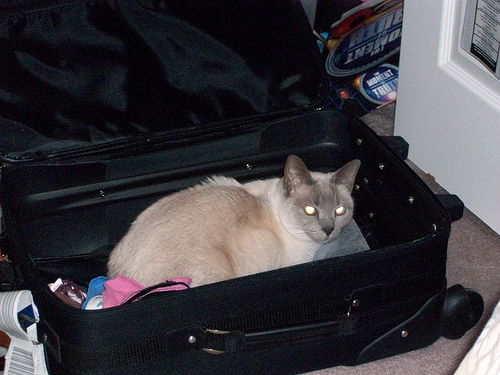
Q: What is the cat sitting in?
A: Suitcase.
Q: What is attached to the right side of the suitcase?
A: Wheels.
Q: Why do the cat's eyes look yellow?
A: Reflection.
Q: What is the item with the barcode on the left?
A: Luggage tag.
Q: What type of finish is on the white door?
A: Paint.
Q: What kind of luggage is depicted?
A: Rolling suitcase.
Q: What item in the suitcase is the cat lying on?
A: Blue jeans.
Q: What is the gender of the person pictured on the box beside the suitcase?
A: Male.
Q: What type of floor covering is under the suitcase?
A: Carpet.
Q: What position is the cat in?
A: Lying.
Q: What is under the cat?
A: Clothing.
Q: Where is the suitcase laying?
A: Floor.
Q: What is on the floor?
A: Carpet.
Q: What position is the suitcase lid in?
A: Open.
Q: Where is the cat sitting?
A: A suitcase.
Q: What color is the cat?
A: Tan.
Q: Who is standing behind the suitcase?
A: No one.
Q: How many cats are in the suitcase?
A: One.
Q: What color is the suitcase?
A: Black.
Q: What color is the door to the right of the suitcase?
A: White.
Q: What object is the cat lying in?
A: Suitcase.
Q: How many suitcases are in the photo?
A: One.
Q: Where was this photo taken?
A: The living area.